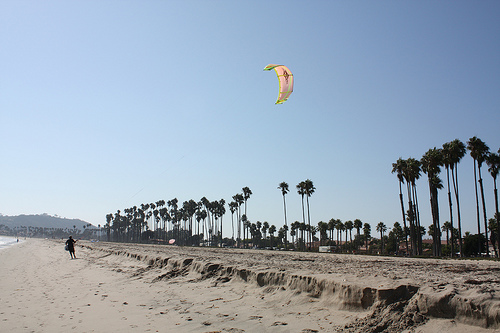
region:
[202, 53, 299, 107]
a yellow kite in the sky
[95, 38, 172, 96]
a clear and blue sky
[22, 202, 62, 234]
a bunch of mountains in the distance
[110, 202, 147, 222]
a bunch of palm trees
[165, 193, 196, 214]
a lot of palm tree leaves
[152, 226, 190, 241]
the skinny trunk of a palm tree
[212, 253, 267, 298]
a ridge made by sand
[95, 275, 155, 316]
a bunch of foot prints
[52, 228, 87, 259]
a person in the distance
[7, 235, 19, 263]
the ocean hitting the short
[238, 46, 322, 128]
a yellow kite in the sky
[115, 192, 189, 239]
a bunch of palm trees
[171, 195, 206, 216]
the leaves of some palm trees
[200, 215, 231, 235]
the skinny trunks of palm trees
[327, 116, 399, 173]
a clear and blue sky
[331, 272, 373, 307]
a ledge made by some sand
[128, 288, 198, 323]
a bunch of foot prints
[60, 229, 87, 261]
a guy standing on the beach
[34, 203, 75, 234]
a mountain in the background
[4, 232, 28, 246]
the shore of the beach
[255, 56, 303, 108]
a kite in the sky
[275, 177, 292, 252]
a palm tree on the edge a beach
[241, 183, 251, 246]
a palm tree on the edge a beach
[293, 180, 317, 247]
palm trees on the edge a beach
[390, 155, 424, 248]
palm trees on the edge a beach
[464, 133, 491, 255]
palm trees on the edge a beach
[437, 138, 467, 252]
palm trees on the edge a beach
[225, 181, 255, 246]
palm trees on the edge a beach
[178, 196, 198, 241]
palm trees on the edge a beach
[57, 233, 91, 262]
a person standing on the beach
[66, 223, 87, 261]
person on the beach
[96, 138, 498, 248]
trees along the beach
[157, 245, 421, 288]
sand elevated from other sand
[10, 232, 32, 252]
people on the beach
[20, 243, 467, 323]
sand area of the beach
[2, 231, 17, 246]
water area of the beach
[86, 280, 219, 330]
imprints from feet in the sand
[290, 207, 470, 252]
buildings behind the trees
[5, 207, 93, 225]
terrain in the distance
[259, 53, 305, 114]
fabric in the air